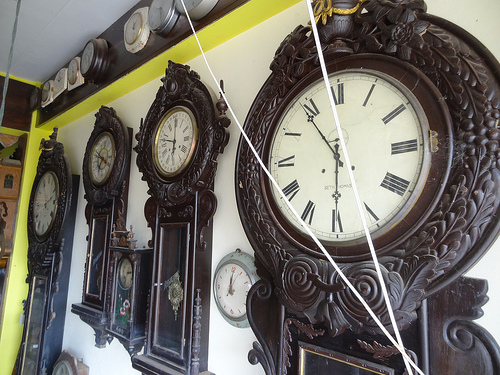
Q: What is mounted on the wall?
A: Clocks.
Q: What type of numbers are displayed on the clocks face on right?
A: Roman numerals.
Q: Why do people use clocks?
A: To tell time.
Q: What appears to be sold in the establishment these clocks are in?
A: Clocks.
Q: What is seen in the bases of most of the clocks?
A: Chimes.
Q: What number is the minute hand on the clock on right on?
A: 6.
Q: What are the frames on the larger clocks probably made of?
A: Wood.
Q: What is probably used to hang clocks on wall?
A: Hooks and brackets.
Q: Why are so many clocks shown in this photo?
A: For variety.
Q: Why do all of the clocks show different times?
A: They aren't set.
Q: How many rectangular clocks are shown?
A: 5.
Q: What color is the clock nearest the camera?
A: Brown.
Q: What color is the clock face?
A: White.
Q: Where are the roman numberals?
A: On the clocks.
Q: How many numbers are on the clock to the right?
A: 12.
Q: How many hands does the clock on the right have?
A: 2.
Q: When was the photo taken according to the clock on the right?
A: 5:54.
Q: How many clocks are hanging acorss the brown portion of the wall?
A: 8.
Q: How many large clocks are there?
A: 4.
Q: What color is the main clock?
A: Brown.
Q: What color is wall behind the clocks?
A: White.